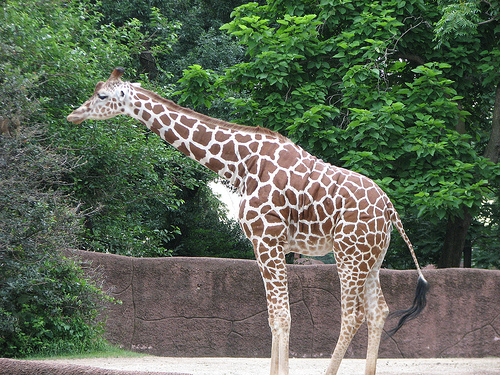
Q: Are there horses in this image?
A: No, there are no horses.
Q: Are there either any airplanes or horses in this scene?
A: No, there are no horses or airplanes.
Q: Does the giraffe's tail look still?
A: Yes, the tail is still.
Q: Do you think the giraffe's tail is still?
A: Yes, the tail is still.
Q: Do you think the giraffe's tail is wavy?
A: No, the tail is still.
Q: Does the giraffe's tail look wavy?
A: No, the tail is still.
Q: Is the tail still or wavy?
A: The tail is still.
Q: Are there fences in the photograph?
A: No, there are no fences.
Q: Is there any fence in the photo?
A: No, there are no fences.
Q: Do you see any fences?
A: No, there are no fences.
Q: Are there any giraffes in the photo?
A: Yes, there is a giraffe.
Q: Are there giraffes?
A: Yes, there is a giraffe.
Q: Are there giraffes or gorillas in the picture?
A: Yes, there is a giraffe.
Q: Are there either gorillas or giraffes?
A: Yes, there is a giraffe.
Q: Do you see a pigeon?
A: No, there are no pigeons.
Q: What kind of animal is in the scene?
A: The animal is a giraffe.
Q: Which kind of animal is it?
A: The animal is a giraffe.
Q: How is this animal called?
A: This is a giraffe.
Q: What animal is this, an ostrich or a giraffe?
A: This is a giraffe.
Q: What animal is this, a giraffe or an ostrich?
A: This is a giraffe.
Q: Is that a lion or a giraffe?
A: That is a giraffe.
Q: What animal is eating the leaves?
A: The animal is a giraffe.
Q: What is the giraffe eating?
A: The giraffe is eating leaves.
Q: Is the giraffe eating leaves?
A: Yes, the giraffe is eating leaves.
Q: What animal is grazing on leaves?
A: The animal is a giraffe.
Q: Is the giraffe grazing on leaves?
A: Yes, the giraffe is grazing on leaves.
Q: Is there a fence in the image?
A: No, there are no fences.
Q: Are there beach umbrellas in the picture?
A: No, there are no beach umbrellas.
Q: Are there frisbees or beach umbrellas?
A: No, there are no beach umbrellas or frisbees.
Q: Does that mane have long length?
A: Yes, the mane is long.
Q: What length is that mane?
A: The mane is long.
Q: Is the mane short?
A: No, the mane is long.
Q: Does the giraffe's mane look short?
A: No, the mane is long.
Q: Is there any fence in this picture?
A: No, there are no fences.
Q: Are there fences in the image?
A: No, there are no fences.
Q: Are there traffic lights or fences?
A: No, there are no fences or traffic lights.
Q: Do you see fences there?
A: No, there are no fences.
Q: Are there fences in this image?
A: No, there are no fences.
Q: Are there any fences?
A: No, there are no fences.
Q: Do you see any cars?
A: No, there are no cars.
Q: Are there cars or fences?
A: No, there are no cars or fences.